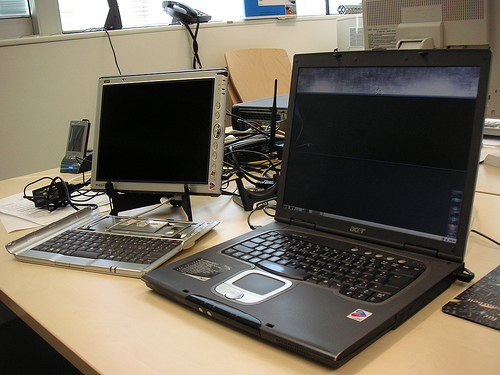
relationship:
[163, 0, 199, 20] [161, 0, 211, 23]
handset in handset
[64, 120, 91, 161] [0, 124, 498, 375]
cellphone on desk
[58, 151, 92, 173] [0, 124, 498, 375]
charger on desk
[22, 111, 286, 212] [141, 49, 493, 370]
cords are behind laptop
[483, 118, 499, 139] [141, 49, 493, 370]
keyboard behind laptop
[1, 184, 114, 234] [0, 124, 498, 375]
paper on desk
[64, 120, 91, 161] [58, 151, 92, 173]
cellphone in charger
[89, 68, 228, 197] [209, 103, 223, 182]
monitor has buttons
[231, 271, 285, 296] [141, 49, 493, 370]
mouse on laptop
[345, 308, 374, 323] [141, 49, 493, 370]
logo on laptop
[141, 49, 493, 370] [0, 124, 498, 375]
laptop on desk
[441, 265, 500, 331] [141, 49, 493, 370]
mouse pad right of laptop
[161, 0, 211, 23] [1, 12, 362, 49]
handset on window sill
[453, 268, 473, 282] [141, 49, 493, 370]
power cord on laptop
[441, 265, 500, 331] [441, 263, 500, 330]
mouse pad has design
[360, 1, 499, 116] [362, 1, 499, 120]
back of monitor